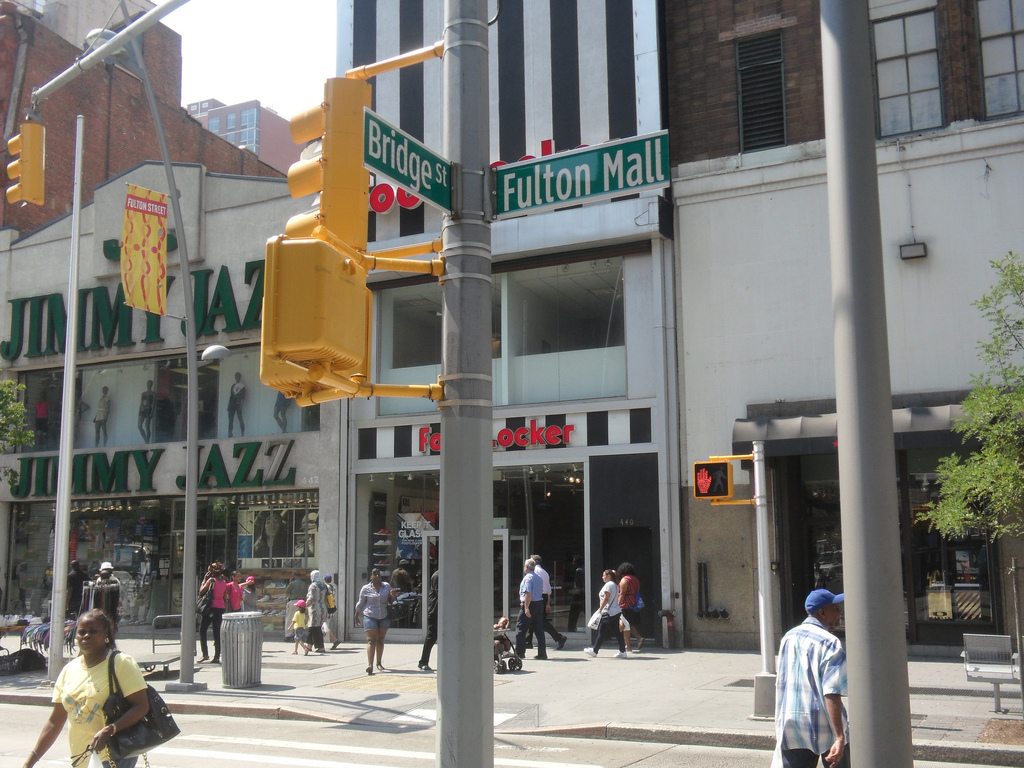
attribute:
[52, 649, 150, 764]
shirt — yellow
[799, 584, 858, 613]
hat — blue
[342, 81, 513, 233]
sign — green, white, bridge st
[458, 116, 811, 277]
sign — white, green, fulton mall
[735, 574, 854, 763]
man — black, blue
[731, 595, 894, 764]
shirt — white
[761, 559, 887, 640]
cap — blue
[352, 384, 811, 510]
sign — black, white, striped, footlocker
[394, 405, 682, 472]
letters — red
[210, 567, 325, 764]
can — silver, trash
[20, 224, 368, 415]
sign — larger, green, jimmy jazz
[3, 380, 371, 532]
one — smaller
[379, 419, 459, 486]
letter — red, f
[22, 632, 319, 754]
shirt — yellow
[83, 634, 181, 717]
shoulder — ladys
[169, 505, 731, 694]
people — walking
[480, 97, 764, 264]
sign — green, white, street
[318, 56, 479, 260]
sign — street, green, white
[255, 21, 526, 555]
light — yellow, painted, traffic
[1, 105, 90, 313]
light — traffic, yellow, painted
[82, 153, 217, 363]
banner — yellow, red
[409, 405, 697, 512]
sign — red, footlocker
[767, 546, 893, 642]
hat — blue, baseball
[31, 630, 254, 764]
shirt — yellow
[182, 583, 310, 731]
trashcan — silver, metal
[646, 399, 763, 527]
sign — orange, walking